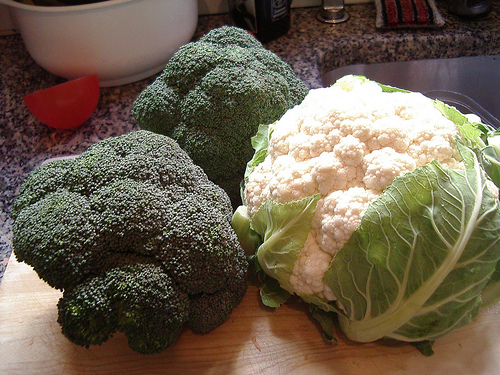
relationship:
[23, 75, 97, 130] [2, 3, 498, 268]
tomato on counter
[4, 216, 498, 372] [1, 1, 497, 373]
board on counter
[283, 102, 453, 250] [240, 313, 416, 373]
cauliflower on cutting board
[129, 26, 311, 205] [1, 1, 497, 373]
broccoli on counter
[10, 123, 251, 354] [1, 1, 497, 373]
broccoli on counter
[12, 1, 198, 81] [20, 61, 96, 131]
bowl by tomato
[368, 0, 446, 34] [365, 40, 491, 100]
scrubber behind sink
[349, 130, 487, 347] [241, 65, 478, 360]
leaf on cauliflower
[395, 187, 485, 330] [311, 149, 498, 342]
vein on leaf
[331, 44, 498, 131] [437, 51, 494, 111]
sink has wall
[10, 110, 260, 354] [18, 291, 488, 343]
broccoli on cutting board